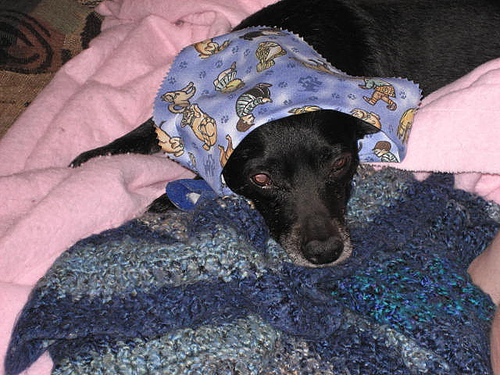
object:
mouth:
[278, 220, 353, 270]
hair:
[312, 13, 364, 53]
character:
[349, 107, 384, 131]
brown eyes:
[249, 170, 279, 191]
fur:
[279, 144, 322, 185]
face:
[222, 110, 377, 273]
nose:
[303, 234, 343, 263]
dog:
[66, 0, 500, 267]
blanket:
[0, 1, 500, 375]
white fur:
[287, 242, 298, 257]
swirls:
[0, 10, 50, 72]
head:
[217, 93, 385, 272]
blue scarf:
[0, 160, 500, 374]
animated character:
[233, 81, 275, 134]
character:
[254, 38, 287, 73]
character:
[357, 76, 396, 111]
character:
[181, 103, 219, 151]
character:
[372, 140, 399, 162]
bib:
[147, 25, 428, 203]